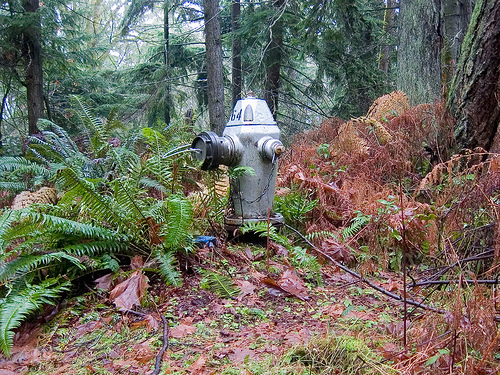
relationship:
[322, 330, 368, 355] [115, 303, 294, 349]
vegetation on floor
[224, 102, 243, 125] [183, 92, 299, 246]
numbers on hydrant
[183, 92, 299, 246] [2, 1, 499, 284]
hydrant in woods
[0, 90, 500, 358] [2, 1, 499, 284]
bushes in woods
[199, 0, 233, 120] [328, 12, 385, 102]
trunks of pine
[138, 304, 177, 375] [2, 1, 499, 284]
sticks in woods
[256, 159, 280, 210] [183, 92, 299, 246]
chain on hydrant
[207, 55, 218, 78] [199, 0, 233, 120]
bark on trunks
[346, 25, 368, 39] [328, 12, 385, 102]
pine needles on pine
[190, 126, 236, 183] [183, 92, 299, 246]
cylinder on hydrant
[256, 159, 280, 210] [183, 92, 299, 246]
chain hanging from hydrant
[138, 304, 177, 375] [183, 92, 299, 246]
sticks near hydrant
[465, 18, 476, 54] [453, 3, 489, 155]
moss on trunk